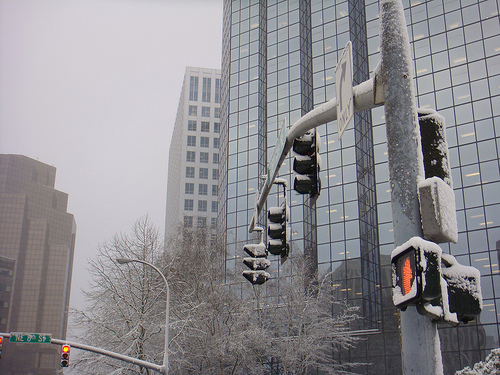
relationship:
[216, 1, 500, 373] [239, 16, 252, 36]
building with window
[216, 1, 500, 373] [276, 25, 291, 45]
building with window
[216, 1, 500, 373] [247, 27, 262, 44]
building with window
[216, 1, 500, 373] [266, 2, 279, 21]
building with window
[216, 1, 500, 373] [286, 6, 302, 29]
building with window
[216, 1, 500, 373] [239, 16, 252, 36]
building has window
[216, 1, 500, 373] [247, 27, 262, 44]
building has window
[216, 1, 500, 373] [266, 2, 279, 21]
building has window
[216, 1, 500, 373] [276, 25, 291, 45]
building has window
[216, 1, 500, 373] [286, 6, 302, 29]
building has window